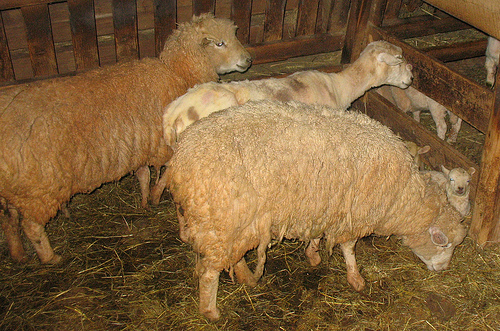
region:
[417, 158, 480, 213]
The baby sheep is small.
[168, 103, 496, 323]
The sheep are fluffy.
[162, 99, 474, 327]
The sheep are white.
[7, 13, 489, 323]
Four sheep are in one section.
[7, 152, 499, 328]
Hay is on the ground.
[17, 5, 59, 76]
brown wooden pen slat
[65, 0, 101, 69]
brown wooden pen slat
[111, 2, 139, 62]
brown wooden pen slat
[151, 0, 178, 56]
brown wooden pen slat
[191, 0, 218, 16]
brown wooden pen slat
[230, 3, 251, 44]
brown wooden pen slat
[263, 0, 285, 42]
brown wooden pen slat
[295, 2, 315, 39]
brown wooden pen slat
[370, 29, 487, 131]
brown wooden pen slat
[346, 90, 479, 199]
brown wooden pen slat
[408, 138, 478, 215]
the baby sheeps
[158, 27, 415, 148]
the shaved sheep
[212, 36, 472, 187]
the eyes of sheep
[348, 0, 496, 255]
the wooden fence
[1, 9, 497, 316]
the sheep in cage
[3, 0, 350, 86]
wall of building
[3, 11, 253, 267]
bronze sheep hair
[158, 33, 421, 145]
sheered sheep in the center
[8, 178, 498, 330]
hay across the ground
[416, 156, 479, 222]
a baby lamb by the fence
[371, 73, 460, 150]
younger sheep on other side of fence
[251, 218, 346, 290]
wool hangs off sheep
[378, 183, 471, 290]
head bent to eat hay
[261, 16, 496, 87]
bottom concrete edge of the barn wall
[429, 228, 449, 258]
an ear shows through the thick coat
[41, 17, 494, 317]
sheep are in stable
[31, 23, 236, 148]
sheep has brown fur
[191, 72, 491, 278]
sheep have white wool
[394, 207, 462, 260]
sheep has brown ears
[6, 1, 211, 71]
wood fence behind sheep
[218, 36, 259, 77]
a sheep's mouth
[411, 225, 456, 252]
the ear of a sheep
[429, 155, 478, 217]
a little baby sheep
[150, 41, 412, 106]
a sheep that is shorn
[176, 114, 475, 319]
a white sheep eating hay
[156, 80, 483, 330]
a sheep in the background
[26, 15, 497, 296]
three sheep standing up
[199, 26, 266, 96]
a sheep eye ball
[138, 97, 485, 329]
wool on the sheep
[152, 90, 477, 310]
fluffy wool on the sheep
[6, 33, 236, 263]
dirty wool on the sheep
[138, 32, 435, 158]
A lamb in a barn.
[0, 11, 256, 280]
A lamb in a barn.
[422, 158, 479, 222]
A lamb in a barn.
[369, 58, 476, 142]
A lamb in a barn.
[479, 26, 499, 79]
A lamb in a barn.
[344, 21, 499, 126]
A plank of wood.A plank of wood.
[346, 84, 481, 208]
A plank of wood.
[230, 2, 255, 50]
A plank of wood.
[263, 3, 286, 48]
A plank of wood.